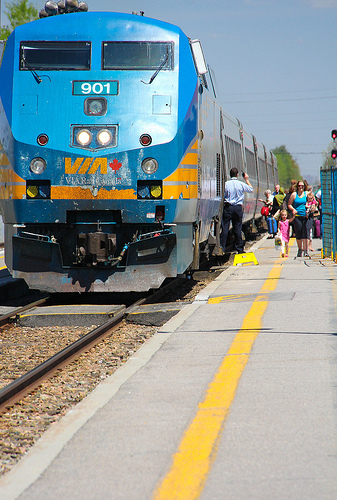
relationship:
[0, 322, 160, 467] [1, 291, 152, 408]
gravel under track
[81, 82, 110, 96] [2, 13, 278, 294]
901 on train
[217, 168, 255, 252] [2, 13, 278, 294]
conductor on train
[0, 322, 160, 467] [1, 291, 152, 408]
gravel for track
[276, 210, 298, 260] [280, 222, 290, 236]
girl wearing pink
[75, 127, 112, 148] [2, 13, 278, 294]
light on train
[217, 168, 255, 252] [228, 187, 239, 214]
conductor in blue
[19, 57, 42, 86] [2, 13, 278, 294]
wipers on train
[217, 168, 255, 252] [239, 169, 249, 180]
conductor holding walkie-talkie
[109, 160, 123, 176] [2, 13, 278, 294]
leaf on train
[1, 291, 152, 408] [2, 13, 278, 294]
track under train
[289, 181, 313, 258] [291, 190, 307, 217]
woman wearing tank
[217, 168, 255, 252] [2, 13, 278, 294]
conductor outside train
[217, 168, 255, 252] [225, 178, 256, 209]
man in shirt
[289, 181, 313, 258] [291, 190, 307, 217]
woman in tank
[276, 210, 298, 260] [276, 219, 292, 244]
child in shirt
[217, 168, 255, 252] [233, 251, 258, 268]
conductor on stool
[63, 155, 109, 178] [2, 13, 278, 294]
via on train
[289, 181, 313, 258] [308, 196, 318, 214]
woman holding baby